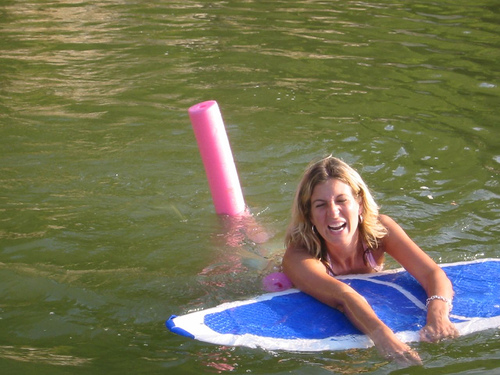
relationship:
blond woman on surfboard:
[277, 150, 461, 368] [163, 256, 498, 351]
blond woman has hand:
[277, 150, 461, 368] [420, 311, 457, 344]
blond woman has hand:
[277, 150, 461, 368] [373, 334, 422, 366]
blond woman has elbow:
[277, 150, 461, 368] [312, 282, 352, 321]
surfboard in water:
[163, 256, 498, 351] [2, 3, 497, 371]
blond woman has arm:
[277, 150, 461, 368] [282, 205, 425, 368]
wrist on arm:
[427, 305, 449, 320] [282, 205, 425, 368]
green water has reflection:
[1, 0, 499, 375] [195, 206, 399, 373]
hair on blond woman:
[286, 154, 387, 256] [277, 150, 461, 368]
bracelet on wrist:
[424, 295, 454, 310] [423, 301, 449, 321]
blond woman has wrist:
[277, 150, 461, 368] [423, 301, 449, 321]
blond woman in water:
[277, 150, 461, 368] [2, 3, 497, 371]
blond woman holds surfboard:
[277, 150, 461, 368] [163, 256, 498, 351]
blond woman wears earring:
[277, 150, 461, 368] [355, 210, 366, 224]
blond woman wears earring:
[277, 150, 461, 368] [305, 220, 320, 238]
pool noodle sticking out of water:
[179, 99, 256, 215] [2, 3, 497, 371]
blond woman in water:
[276, 157, 455, 361] [71, 200, 163, 297]